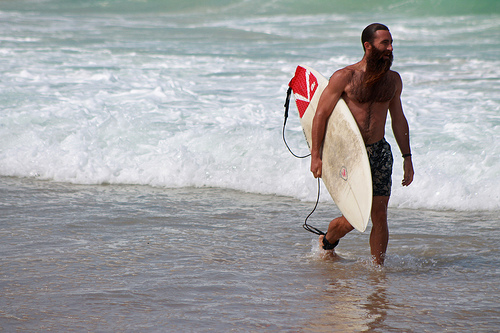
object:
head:
[362, 23, 393, 63]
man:
[311, 23, 414, 267]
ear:
[364, 41, 372, 49]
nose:
[386, 43, 393, 52]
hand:
[310, 157, 321, 178]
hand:
[402, 158, 414, 186]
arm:
[311, 68, 346, 149]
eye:
[383, 41, 388, 44]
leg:
[370, 141, 392, 264]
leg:
[326, 214, 353, 243]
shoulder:
[390, 70, 402, 96]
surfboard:
[290, 63, 373, 232]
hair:
[361, 23, 389, 52]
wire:
[283, 87, 311, 158]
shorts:
[365, 137, 393, 196]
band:
[401, 153, 411, 158]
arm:
[390, 71, 411, 153]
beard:
[363, 45, 393, 87]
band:
[322, 232, 340, 250]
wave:
[2, 1, 499, 211]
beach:
[1, 176, 499, 333]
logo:
[287, 65, 319, 119]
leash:
[303, 178, 326, 235]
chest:
[346, 70, 397, 104]